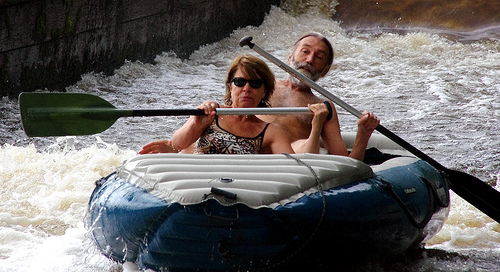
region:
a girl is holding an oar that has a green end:
[16, 90, 333, 137]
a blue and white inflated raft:
[83, 129, 452, 270]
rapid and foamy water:
[1, 13, 499, 268]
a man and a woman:
[141, 28, 376, 156]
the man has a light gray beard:
[285, 31, 335, 90]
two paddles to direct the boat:
[16, 33, 498, 226]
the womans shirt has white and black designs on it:
[193, 110, 270, 155]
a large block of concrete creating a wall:
[0, 0, 275, 100]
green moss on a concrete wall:
[31, 8, 85, 50]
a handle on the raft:
[198, 183, 242, 223]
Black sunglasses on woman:
[231, 75, 266, 87]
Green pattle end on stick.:
[16, 87, 126, 140]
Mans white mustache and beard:
[286, 57, 321, 87]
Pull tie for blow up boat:
[204, 186, 238, 203]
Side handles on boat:
[383, 172, 452, 227]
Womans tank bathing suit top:
[198, 116, 274, 153]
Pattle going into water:
[443, 156, 498, 227]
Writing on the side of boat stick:
[271, 59, 302, 81]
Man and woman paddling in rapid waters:
[18, 30, 498, 270]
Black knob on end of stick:
[238, 32, 255, 51]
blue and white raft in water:
[85, 124, 453, 261]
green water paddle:
[12, 79, 332, 141]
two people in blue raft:
[80, 24, 457, 267]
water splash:
[52, 140, 107, 151]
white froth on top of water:
[415, 77, 454, 107]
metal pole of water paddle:
[212, 95, 319, 118]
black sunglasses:
[223, 73, 270, 88]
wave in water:
[368, 28, 448, 60]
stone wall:
[0, 0, 273, 100]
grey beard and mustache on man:
[282, 55, 327, 95]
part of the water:
[463, 28, 497, 74]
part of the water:
[406, 45, 439, 90]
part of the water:
[465, 100, 492, 160]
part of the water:
[382, 91, 403, 117]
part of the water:
[456, 223, 485, 248]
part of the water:
[27, 153, 69, 196]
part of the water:
[173, 74, 196, 97]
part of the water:
[127, 126, 157, 138]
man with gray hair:
[269, 28, 377, 153]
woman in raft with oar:
[12, 53, 333, 157]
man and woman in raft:
[75, 29, 454, 261]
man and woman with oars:
[12, 28, 498, 224]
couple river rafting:
[8, 23, 498, 267]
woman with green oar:
[9, 64, 334, 164]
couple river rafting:
[4, 13, 498, 268]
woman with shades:
[134, 49, 334, 156]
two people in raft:
[17, 31, 498, 217]